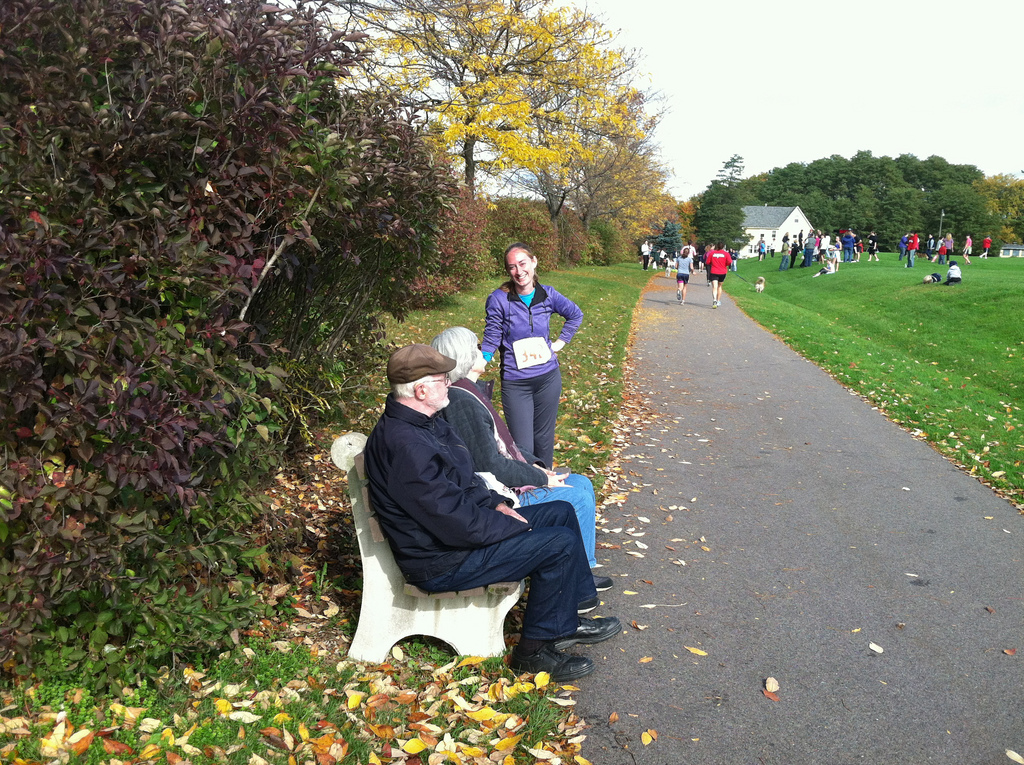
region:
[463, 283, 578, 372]
The purple jacket the person is wearing.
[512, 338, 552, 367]
The white sticker on the person's purple jacket.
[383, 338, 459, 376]
The brown hat the older man is wearing.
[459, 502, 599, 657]
The dark blue pants the older man is wearing.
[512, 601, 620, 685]
The black boots the older man is wearing.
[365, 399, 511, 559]
The dark colored jacket the older man is wearing.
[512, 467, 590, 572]
The light blue pants the older woman is wearing.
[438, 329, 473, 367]
The white hair of the older woman.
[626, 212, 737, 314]
The people running on the sidewalk.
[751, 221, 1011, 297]
The group of people standing on the grass.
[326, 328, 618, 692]
two people on a bench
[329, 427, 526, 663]
bench is painted white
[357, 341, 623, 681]
man is wearing a hat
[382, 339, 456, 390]
the hat is brown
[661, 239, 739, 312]
two people running on cement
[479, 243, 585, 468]
woman wearing purple jacket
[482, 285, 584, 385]
jacket has a sign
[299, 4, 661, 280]
tree has yellow leaves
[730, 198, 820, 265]
house has gray roof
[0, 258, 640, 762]
fallen leaves on grass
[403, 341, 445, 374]
Brown hat on top of man's head.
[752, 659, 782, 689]
Leaves on top of the sidewalk.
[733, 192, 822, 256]
White house in the back of the trees.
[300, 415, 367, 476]
White piece of trash on the ground.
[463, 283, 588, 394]
Purple jacket with blue shirt underneath.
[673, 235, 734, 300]
Group of people running around track.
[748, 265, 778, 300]
Dog running in the grass.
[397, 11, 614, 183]
Tree with thin light green flowers.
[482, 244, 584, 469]
woman in purple jacket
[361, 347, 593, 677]
man in blue jacket sitting on bench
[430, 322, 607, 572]
old lady with grey hair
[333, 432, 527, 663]
white park bench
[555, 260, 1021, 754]
asphalt pavement in a park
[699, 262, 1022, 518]
green grass in a park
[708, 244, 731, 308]
man walking in park with red shirt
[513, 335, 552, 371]
a white sign on a woman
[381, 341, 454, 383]
a brown hat on a man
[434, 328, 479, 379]
an old lady's white hair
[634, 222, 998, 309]
people gathered for a marathon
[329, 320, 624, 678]
older couple sitting on a bench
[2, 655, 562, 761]
leaves falling from bush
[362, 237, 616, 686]
marathon runner talking to older couple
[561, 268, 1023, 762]
concrete path leading to a building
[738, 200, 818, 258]
white building in the distance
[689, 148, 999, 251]
stand of evergreens behind white building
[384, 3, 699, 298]
autumn leaves on trees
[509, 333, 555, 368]
paper with number of runner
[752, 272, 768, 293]
dog in the fields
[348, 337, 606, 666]
man and woman on a bench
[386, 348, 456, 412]
the man is wearing a brown hat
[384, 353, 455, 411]
the man is wearing eyeglasses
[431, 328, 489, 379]
the woman has gray hair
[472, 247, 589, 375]
the woman is wearing a purple jacket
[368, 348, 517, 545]
the man is wearing a blue jacket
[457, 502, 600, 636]
the pants are dark blue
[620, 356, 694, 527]
leaves are on a sidewalk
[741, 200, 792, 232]
the shingled roof is gray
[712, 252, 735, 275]
the person is wearing a red shirt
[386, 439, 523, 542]
arm of a man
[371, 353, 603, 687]
a person is sitting